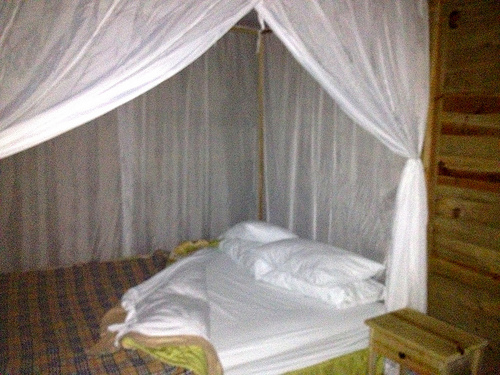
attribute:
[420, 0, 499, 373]
wall — wood, wooden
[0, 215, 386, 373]
bed — plaid, white 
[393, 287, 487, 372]
table — wooden 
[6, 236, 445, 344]
bed — wood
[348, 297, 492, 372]
nightstand — brown 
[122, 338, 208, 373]
green object — small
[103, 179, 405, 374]
bed — partially made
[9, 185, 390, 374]
bed — beautiful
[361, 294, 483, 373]
table — wooden 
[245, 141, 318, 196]
wall — white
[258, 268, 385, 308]
pillows — white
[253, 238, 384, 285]
pillows — white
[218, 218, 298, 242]
pillows — white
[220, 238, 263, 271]
pillows — white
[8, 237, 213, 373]
cover — turned down 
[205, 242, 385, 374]
sheet — white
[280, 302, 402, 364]
bed frame — wood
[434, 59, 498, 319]
wall — wooden 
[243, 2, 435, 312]
curtain — tied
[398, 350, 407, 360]
knob — black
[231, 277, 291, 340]
sheets — crisp clean, white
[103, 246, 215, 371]
covers — turned down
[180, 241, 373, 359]
sheets — white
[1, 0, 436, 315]
curtains — white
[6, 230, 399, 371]
blanket — orange, black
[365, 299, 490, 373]
table — wood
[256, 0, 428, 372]
curtain — tied back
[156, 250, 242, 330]
sheet — white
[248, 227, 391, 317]
pillows — beautiful